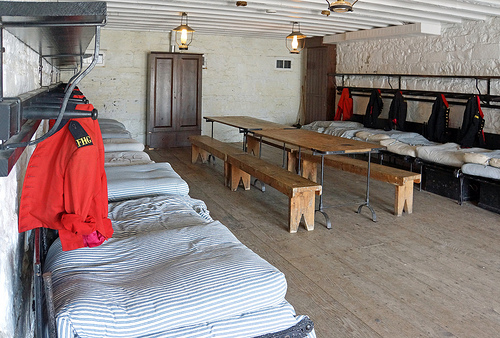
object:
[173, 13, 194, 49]
lights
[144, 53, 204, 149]
cabinet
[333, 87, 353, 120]
coat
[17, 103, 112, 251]
jacket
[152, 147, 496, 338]
floor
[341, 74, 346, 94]
metal posts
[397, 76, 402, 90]
metal posts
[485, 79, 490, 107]
metal posts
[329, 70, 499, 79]
bars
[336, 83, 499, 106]
bar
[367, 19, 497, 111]
walls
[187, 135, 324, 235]
bench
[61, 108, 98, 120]
hook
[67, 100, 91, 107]
hook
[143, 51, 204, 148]
door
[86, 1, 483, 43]
vent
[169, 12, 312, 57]
fixtures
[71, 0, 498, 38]
ceiling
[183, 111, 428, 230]
table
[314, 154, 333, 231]
leg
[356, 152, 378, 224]
leg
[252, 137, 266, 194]
leg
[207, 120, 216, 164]
leg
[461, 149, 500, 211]
bed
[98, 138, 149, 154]
bed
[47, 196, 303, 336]
mattresses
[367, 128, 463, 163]
cots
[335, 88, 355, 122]
jacket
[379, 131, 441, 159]
bed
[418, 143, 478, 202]
bed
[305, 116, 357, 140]
bed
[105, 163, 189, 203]
mattress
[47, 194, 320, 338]
bed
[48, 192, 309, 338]
sheets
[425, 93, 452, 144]
jacket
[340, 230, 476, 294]
hardwood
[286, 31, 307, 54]
lamp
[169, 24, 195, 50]
lamp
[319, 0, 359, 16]
lamp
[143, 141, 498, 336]
wood floor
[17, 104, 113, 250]
red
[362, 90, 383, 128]
jacket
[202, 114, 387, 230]
wooden table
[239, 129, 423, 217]
benches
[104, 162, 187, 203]
bed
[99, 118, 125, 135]
bed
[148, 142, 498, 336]
boards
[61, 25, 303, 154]
wall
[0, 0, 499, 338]
quarters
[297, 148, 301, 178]
legs